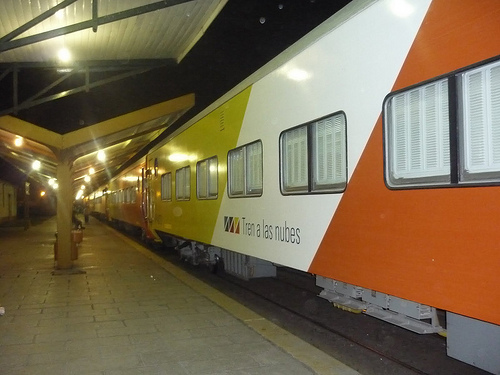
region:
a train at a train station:
[86, 2, 491, 369]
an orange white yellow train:
[94, 52, 496, 332]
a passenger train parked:
[79, 41, 476, 371]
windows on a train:
[280, 75, 467, 224]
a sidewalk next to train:
[12, 136, 182, 373]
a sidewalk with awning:
[5, 82, 233, 340]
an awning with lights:
[21, 87, 174, 284]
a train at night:
[115, 50, 419, 373]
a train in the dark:
[119, 17, 431, 349]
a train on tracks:
[54, 52, 421, 319]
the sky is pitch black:
[233, 42, 258, 60]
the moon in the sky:
[250, 10, 273, 28]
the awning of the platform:
[3, 84, 205, 277]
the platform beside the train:
[28, 258, 230, 372]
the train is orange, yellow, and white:
[111, 2, 499, 371]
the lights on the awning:
[71, 150, 113, 207]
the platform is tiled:
[52, 290, 156, 371]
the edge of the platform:
[134, 242, 308, 373]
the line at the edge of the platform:
[170, 257, 312, 367]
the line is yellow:
[228, 295, 403, 373]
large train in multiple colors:
[113, 99, 423, 255]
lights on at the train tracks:
[24, 105, 141, 262]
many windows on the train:
[144, 110, 491, 162]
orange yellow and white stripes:
[181, 104, 456, 245]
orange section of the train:
[351, 68, 478, 290]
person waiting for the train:
[64, 197, 98, 232]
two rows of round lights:
[18, 131, 135, 221]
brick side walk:
[47, 275, 193, 359]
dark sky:
[205, 12, 307, 40]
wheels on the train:
[103, 210, 231, 270]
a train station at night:
[2, 82, 185, 373]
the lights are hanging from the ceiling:
[9, 130, 119, 220]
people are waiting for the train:
[65, 202, 90, 248]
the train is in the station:
[84, 11, 496, 366]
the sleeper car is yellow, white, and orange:
[145, 17, 495, 339]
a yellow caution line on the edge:
[90, 213, 348, 373]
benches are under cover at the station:
[51, 221, 84, 281]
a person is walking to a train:
[72, 199, 110, 246]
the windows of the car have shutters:
[272, 111, 350, 196]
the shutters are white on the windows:
[381, 60, 499, 190]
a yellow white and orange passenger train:
[129, 10, 494, 332]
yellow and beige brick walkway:
[32, 284, 209, 374]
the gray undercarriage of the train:
[216, 255, 497, 362]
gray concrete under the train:
[260, 293, 353, 353]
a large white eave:
[17, 82, 192, 272]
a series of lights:
[77, 157, 107, 204]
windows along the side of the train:
[146, 100, 498, 187]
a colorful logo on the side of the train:
[215, 214, 242, 235]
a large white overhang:
[3, 14, 192, 69]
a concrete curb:
[199, 280, 357, 372]